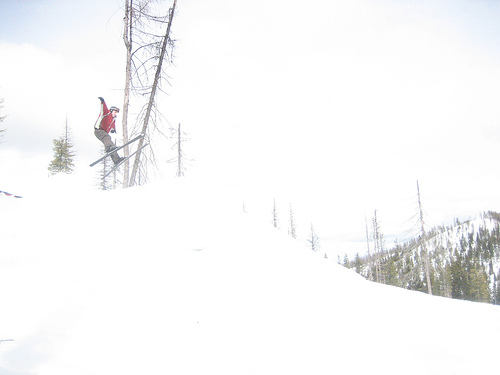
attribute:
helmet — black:
[109, 103, 119, 113]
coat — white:
[92, 101, 117, 132]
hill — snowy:
[2, 181, 499, 369]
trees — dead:
[103, 0, 174, 187]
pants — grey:
[94, 131, 124, 170]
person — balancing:
[65, 79, 181, 211]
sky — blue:
[9, 4, 51, 45]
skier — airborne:
[87, 82, 155, 215]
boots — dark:
[104, 145, 126, 169]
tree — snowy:
[113, 2, 173, 176]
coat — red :
[95, 95, 117, 132]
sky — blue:
[0, 0, 496, 264]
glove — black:
[94, 95, 110, 102]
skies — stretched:
[91, 134, 148, 179]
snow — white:
[152, 259, 274, 372]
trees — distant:
[365, 237, 495, 301]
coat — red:
[94, 97, 118, 135]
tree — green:
[465, 263, 491, 302]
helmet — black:
[98, 103, 120, 118]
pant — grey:
[90, 127, 120, 159]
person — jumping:
[81, 92, 151, 167]